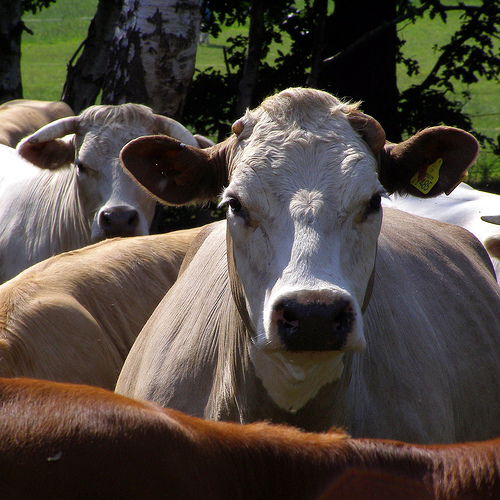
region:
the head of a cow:
[115, 73, 490, 365]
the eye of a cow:
[211, 183, 253, 232]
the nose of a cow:
[268, 288, 356, 355]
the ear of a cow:
[382, 117, 482, 207]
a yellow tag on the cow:
[405, 153, 447, 197]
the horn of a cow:
[15, 111, 83, 153]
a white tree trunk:
[96, 0, 203, 117]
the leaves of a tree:
[417, 2, 499, 107]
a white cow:
[0, 97, 215, 279]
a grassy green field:
[18, 0, 498, 185]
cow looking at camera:
[119, 86, 478, 391]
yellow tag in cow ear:
[407, 148, 449, 201]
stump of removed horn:
[222, 115, 257, 147]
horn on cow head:
[22, 109, 86, 153]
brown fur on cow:
[59, 376, 268, 479]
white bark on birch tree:
[132, 4, 196, 72]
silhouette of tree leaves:
[409, 38, 487, 118]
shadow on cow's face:
[272, 205, 304, 275]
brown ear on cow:
[115, 128, 231, 212]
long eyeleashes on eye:
[209, 188, 249, 228]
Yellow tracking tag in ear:
[366, 122, 490, 223]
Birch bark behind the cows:
[107, 6, 260, 168]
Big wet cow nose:
[263, 284, 383, 373]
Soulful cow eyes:
[205, 166, 399, 261]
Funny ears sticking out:
[119, 93, 499, 240]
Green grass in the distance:
[13, 5, 121, 137]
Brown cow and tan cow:
[55, 246, 367, 496]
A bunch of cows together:
[8, 84, 420, 486]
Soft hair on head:
[202, 82, 387, 256]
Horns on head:
[16, 98, 206, 153]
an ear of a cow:
[389, 128, 480, 196]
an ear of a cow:
[121, 137, 215, 204]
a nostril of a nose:
[263, 289, 304, 334]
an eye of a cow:
[215, 182, 250, 226]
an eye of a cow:
[354, 187, 389, 219]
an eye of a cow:
[71, 157, 93, 178]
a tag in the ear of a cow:
[416, 156, 443, 192]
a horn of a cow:
[29, 118, 69, 144]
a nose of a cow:
[101, 205, 141, 234]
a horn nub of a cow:
[227, 117, 249, 137]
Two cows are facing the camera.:
[35, 100, 450, 377]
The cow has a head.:
[115, 84, 482, 379]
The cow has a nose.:
[265, 280, 355, 355]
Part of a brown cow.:
[25, 400, 175, 495]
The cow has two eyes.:
[215, 170, 393, 226]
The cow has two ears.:
[113, 120, 481, 206]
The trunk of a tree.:
[67, 1, 202, 101]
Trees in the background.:
[0, 2, 496, 105]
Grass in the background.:
[41, 17, 66, 63]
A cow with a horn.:
[15, 100, 82, 162]